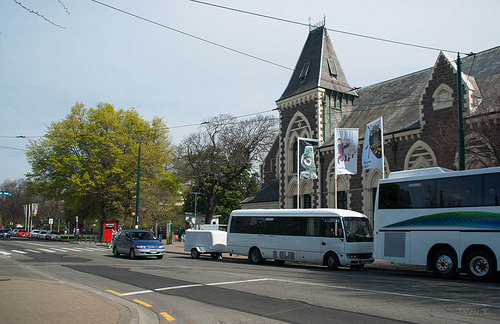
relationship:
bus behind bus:
[226, 209, 374, 270] [369, 163, 499, 284]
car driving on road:
[110, 229, 166, 259] [98, 267, 333, 317]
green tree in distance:
[33, 108, 183, 245] [5, 59, 278, 279]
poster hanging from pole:
[300, 143, 315, 180] [294, 136, 321, 203]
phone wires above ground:
[190, 0, 472, 56] [0, 236, 499, 322]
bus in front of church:
[373, 161, 499, 273] [290, 14, 497, 194]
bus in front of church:
[226, 209, 374, 270] [290, 14, 497, 194]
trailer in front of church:
[174, 226, 225, 256] [290, 14, 497, 194]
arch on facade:
[397, 137, 438, 172] [239, 19, 499, 226]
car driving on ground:
[109, 223, 171, 262] [0, 236, 499, 322]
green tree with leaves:
[23, 101, 176, 242] [26, 102, 189, 214]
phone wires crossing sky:
[85, 0, 294, 70] [0, 0, 498, 182]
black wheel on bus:
[462, 245, 494, 282] [372, 166, 500, 280]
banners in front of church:
[316, 130, 481, 174] [279, 47, 490, 184]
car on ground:
[110, 229, 166, 259] [0, 236, 499, 322]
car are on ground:
[110, 229, 166, 259] [0, 236, 499, 322]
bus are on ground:
[226, 209, 374, 270] [0, 236, 499, 322]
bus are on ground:
[372, 166, 500, 280] [0, 236, 499, 322]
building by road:
[241, 16, 496, 216] [5, 219, 497, 322]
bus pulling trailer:
[226, 209, 374, 270] [180, 225, 232, 256]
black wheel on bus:
[429, 244, 459, 280] [369, 163, 499, 284]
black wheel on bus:
[461, 244, 496, 282] [369, 163, 499, 284]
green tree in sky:
[23, 101, 176, 242] [0, 0, 498, 182]